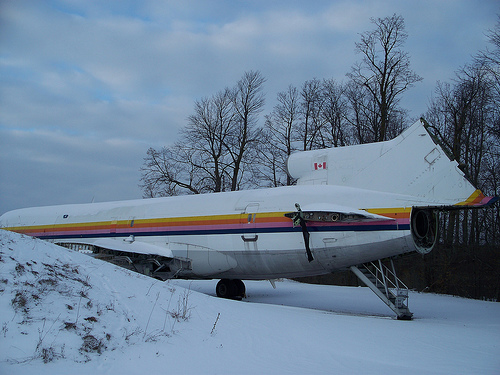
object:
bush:
[423, 250, 497, 299]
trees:
[137, 13, 499, 246]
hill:
[0, 229, 187, 362]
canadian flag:
[310, 161, 327, 171]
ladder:
[349, 263, 414, 321]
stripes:
[25, 218, 411, 239]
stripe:
[33, 223, 411, 240]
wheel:
[212, 279, 245, 300]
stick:
[210, 309, 222, 333]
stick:
[183, 288, 190, 319]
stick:
[180, 287, 184, 317]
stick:
[175, 296, 180, 320]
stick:
[142, 289, 160, 339]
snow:
[0, 229, 499, 374]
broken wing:
[280, 205, 386, 232]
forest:
[136, 10, 499, 286]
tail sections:
[280, 117, 493, 211]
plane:
[0, 117, 493, 322]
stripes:
[1, 207, 411, 232]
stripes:
[10, 212, 408, 235]